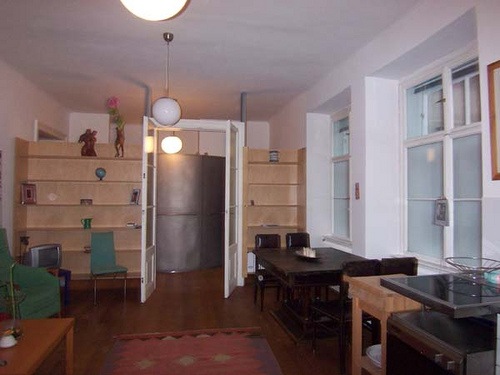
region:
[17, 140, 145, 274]
a wooden shelf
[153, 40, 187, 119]
a light hanging from the ceiling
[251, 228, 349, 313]
a table and chairs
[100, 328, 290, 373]
a rug on the floor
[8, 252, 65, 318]
a green chair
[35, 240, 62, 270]
a silver television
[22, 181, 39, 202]
a picture frame on the shelf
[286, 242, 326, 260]
candles on the table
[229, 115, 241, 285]
a white door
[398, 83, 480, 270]
a window behind the table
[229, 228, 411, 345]
dark wood table and four chairs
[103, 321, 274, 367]
red rug on floor with geometric design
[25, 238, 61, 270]
small television on small table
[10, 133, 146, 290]
wall of shelves to divide rooms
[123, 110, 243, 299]
large double doorway with white doors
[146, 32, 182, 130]
round light fixtures hang from ceiling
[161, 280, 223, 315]
floor looks like wood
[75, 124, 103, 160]
brown sculpture on top shelf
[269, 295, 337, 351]
dark colored rug under dinging room table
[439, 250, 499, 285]
basket made of silver wire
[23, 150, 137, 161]
light brown wooden shelf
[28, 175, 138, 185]
light brown wooden shelf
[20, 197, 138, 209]
light brown wooden shelf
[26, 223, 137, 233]
light brown wooden shelf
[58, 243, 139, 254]
light brown wooden shelf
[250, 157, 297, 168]
light brown wooden shelf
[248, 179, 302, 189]
light brown wooden shelf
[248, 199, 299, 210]
light brown wooden shelf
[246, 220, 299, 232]
light brown wooden shelf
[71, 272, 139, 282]
light brown wooden shelf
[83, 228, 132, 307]
blue chair placed in front of bookcase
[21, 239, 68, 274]
small television sitting on table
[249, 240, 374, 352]
wood table against wall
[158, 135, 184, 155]
globe light hanging from ceiling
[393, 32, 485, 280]
double wood framed window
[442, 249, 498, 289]
metal basket sitting on counter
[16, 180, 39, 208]
picture frame sitting on bookcase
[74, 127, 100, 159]
statue sitting on bookcase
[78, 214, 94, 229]
small green pitcher sitting on bookcase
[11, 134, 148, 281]
light wood bookcase behind door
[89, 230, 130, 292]
a green chair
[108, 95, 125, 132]
a pink flower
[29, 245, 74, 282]
a television sitting on a small table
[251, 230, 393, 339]
a dark colored table and chairs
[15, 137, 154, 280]
a shelf on the wall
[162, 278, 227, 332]
hard wood flooring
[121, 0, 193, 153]
lights hanging from the ceiling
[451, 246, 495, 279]
a basket on the counter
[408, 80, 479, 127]
windows in the wall